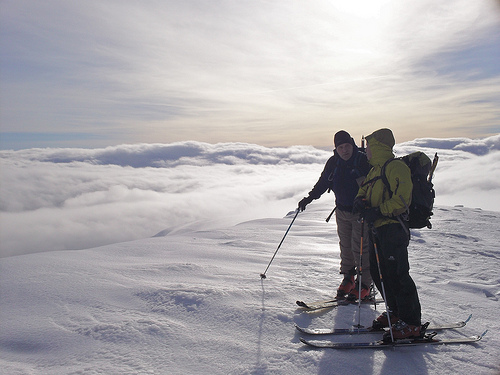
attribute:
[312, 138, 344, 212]
ski jacket — green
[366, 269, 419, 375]
pants — dark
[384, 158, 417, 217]
jacket — yellow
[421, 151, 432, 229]
backpack — black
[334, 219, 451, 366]
poles — white, orange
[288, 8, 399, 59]
sun — shining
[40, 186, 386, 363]
snow — covering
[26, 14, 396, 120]
clouds — spreading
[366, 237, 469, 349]
pants — black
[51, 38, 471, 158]
sky — cloudy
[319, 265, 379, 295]
boots — orange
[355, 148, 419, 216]
coat — green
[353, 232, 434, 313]
pants — black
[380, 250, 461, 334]
pants — black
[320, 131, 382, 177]
hat — black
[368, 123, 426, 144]
hat — gray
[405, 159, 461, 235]
bookbag — black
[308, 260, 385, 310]
sneakers — orange